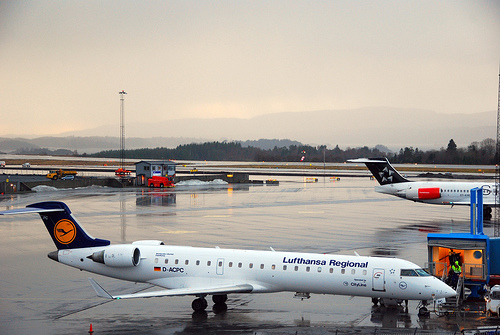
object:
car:
[145, 174, 173, 190]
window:
[337, 266, 346, 275]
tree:
[0, 139, 500, 165]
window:
[399, 267, 418, 276]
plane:
[0, 200, 459, 313]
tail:
[0, 200, 111, 251]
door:
[371, 269, 387, 293]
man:
[446, 258, 466, 290]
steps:
[442, 299, 457, 305]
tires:
[189, 297, 207, 313]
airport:
[0, 169, 499, 335]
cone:
[46, 243, 149, 281]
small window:
[293, 265, 299, 272]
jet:
[370, 180, 404, 201]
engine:
[85, 244, 143, 268]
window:
[247, 262, 253, 270]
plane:
[343, 155, 497, 220]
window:
[256, 263, 265, 270]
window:
[268, 263, 277, 269]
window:
[281, 263, 288, 272]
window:
[291, 264, 299, 271]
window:
[339, 267, 347, 276]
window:
[304, 266, 312, 273]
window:
[257, 262, 265, 270]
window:
[193, 260, 202, 267]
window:
[163, 259, 170, 265]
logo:
[51, 218, 76, 247]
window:
[304, 264, 311, 271]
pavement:
[0, 157, 498, 177]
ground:
[0, 153, 499, 334]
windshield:
[416, 269, 427, 278]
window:
[360, 269, 370, 276]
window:
[236, 262, 242, 269]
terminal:
[0, 199, 125, 281]